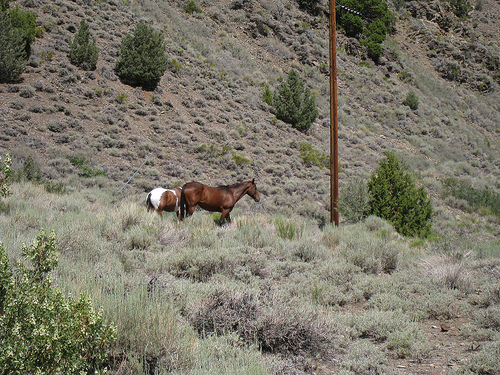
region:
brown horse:
[142, 157, 270, 235]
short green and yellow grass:
[17, 93, 108, 151]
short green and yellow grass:
[253, 298, 311, 346]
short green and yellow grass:
[139, 237, 212, 311]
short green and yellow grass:
[346, 273, 463, 339]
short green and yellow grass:
[101, 260, 195, 329]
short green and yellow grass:
[228, 87, 290, 117]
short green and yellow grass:
[357, 59, 449, 132]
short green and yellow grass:
[378, 116, 494, 192]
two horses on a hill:
[135, 175, 265, 223]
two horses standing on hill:
[135, 175, 260, 225]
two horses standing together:
[137, 166, 266, 221]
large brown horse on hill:
[178, 174, 262, 223]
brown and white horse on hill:
[145, 185, 180, 213]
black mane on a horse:
[212, 180, 237, 190]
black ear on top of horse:
[251, 178, 255, 183]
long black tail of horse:
[170, 189, 191, 214]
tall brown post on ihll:
[323, 3, 340, 228]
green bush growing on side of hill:
[115, 16, 172, 87]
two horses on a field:
[147, 148, 264, 231]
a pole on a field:
[307, 8, 349, 240]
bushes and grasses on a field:
[27, 220, 472, 362]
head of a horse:
[247, 173, 264, 209]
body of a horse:
[175, 184, 240, 209]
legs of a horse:
[176, 210, 234, 231]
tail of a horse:
[175, 186, 190, 220]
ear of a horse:
[247, 173, 259, 183]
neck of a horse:
[230, 176, 247, 208]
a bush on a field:
[109, 19, 172, 101]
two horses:
[144, 177, 256, 226]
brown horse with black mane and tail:
[175, 178, 261, 226]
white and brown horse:
[146, 186, 178, 223]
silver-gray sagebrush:
[252, 307, 328, 360]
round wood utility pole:
[329, 1, 337, 226]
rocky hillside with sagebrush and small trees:
[5, 0, 497, 204]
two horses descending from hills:
[0, 3, 499, 372]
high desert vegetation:
[0, 233, 121, 374]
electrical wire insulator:
[337, 4, 361, 17]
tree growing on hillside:
[367, 153, 434, 241]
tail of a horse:
[140, 190, 155, 214]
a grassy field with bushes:
[16, 218, 491, 373]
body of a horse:
[134, 183, 180, 212]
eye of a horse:
[254, 185, 260, 195]